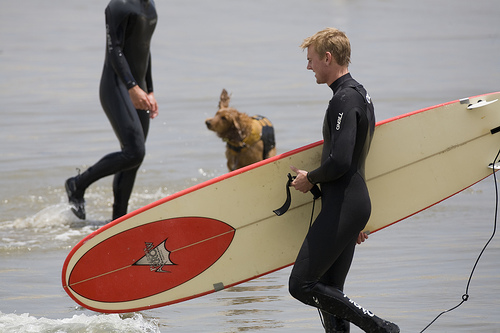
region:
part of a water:
[209, 18, 240, 55]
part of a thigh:
[296, 233, 316, 279]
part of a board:
[142, 217, 179, 267]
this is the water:
[202, 13, 284, 82]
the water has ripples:
[388, 260, 434, 297]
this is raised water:
[11, 310, 155, 332]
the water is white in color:
[19, 310, 118, 330]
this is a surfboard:
[25, 181, 312, 309]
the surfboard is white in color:
[232, 187, 257, 213]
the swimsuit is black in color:
[329, 161, 361, 231]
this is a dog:
[206, 93, 280, 163]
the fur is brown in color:
[236, 145, 250, 157]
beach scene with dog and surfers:
[2, 3, 491, 332]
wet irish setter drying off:
[198, 101, 269, 173]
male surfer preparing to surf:
[285, 26, 374, 331]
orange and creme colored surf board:
[59, 90, 497, 331]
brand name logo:
[132, 233, 175, 283]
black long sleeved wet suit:
[290, 76, 402, 330]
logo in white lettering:
[332, 106, 344, 138]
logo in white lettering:
[338, 295, 378, 321]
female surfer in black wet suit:
[57, 0, 164, 217]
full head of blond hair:
[300, 26, 353, 71]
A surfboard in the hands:
[59, 97, 492, 309]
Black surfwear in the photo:
[291, 87, 371, 313]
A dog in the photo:
[195, 94, 282, 167]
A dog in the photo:
[319, 308, 396, 330]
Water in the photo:
[212, 17, 281, 74]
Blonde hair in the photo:
[308, 16, 360, 66]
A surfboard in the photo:
[60, 195, 284, 320]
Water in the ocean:
[388, 48, 458, 77]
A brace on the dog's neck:
[219, 139, 266, 157]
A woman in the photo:
[61, 7, 173, 223]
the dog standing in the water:
[203, 91, 277, 168]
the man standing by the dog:
[63, 1, 162, 219]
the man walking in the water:
[291, 30, 397, 332]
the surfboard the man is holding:
[60, 90, 499, 315]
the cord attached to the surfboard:
[277, 165, 498, 331]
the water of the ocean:
[3, 3, 496, 330]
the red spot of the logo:
[69, 215, 234, 299]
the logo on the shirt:
[129, 231, 184, 275]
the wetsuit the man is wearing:
[287, 70, 398, 327]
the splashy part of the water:
[13, 193, 80, 242]